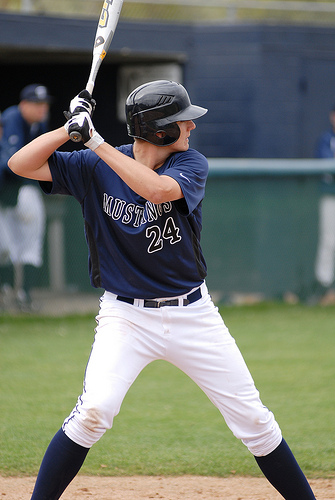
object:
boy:
[7, 79, 317, 500]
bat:
[69, 0, 124, 142]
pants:
[61, 278, 283, 457]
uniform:
[31, 143, 316, 500]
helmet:
[124, 79, 208, 148]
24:
[146, 217, 182, 254]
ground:
[57, 476, 285, 500]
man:
[0, 82, 49, 178]